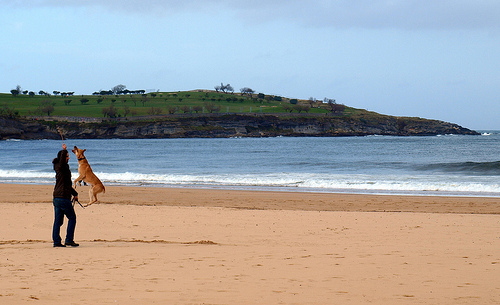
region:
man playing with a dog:
[51, 124, 106, 249]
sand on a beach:
[0, 179, 497, 304]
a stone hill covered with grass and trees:
[0, 87, 480, 137]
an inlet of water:
[1, 130, 498, 191]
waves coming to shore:
[2, 167, 498, 197]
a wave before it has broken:
[426, 158, 498, 175]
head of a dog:
[71, 145, 88, 159]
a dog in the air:
[70, 143, 106, 208]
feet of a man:
[52, 240, 79, 247]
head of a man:
[56, 148, 70, 165]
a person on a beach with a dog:
[40, 125, 99, 257]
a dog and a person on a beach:
[46, 139, 108, 259]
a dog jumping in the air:
[66, 137, 119, 214]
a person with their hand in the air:
[43, 116, 80, 253]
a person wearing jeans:
[51, 191, 76, 249]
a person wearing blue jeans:
[49, 193, 81, 245]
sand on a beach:
[121, 204, 456, 287]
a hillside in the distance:
[6, 83, 498, 144]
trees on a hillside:
[3, 77, 263, 101]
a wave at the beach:
[153, 159, 491, 209]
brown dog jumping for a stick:
[45, 123, 128, 211]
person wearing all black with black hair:
[32, 116, 77, 253]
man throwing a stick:
[41, 105, 72, 175]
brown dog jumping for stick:
[40, 110, 110, 277]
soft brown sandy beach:
[138, 187, 445, 297]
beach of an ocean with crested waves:
[145, 127, 485, 202]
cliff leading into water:
[88, 95, 421, 141]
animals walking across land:
[16, 75, 234, 115]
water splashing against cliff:
[475, 115, 493, 155]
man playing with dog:
[31, 125, 127, 267]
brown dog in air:
[73, 145, 104, 202]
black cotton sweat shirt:
[52, 161, 77, 197]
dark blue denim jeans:
[51, 198, 78, 243]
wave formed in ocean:
[303, 155, 498, 176]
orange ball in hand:
[61, 142, 66, 149]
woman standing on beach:
[46, 146, 82, 249]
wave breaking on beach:
[1, 165, 498, 197]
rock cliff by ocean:
[1, 114, 476, 137]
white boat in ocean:
[480, 132, 491, 137]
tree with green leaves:
[215, 81, 237, 92]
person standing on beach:
[34, 140, 81, 243]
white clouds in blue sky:
[31, 22, 75, 45]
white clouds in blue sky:
[47, 22, 93, 64]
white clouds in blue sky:
[437, 24, 475, 68]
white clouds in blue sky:
[410, 55, 451, 97]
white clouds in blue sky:
[293, 33, 354, 75]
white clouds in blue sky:
[231, 19, 284, 68]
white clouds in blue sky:
[175, 28, 241, 67]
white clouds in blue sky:
[128, 14, 185, 48]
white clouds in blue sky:
[91, 28, 130, 59]